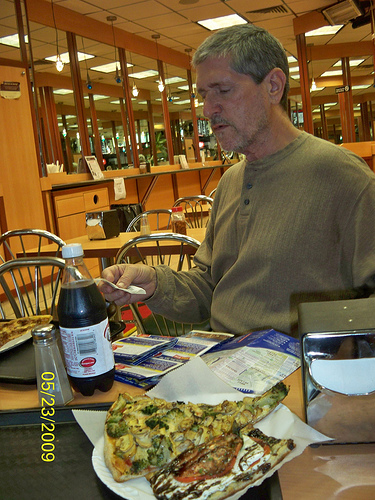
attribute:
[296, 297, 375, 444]
napkin dispenser — chrome, silver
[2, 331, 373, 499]
table — wooden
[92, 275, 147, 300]
napkin — white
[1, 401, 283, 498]
food tray — black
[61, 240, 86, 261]
bottle cap — white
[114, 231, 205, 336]
chair — chrome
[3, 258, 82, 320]
chair — chrome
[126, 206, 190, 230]
chair — chrome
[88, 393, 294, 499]
paper plate — white